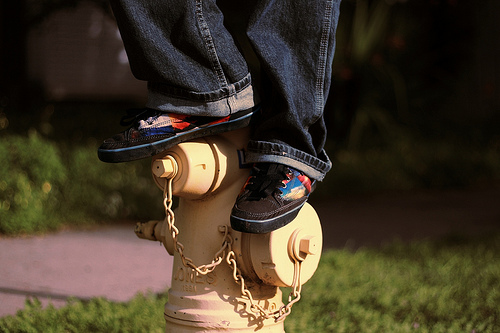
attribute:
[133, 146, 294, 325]
hydrant — fire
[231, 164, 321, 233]
shoestrings — black, tennis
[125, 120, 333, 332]
fire hydrant — light yellow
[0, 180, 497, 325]
sidewalk — cement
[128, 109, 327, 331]
hydrant — fire, yellow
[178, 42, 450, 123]
jeans — dark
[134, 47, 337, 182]
pants — rolled up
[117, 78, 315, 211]
black shoes — his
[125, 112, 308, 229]
shoes — black, his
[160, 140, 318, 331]
hydrant — fire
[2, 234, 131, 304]
sidewalk — empty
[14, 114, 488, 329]
grass — dark green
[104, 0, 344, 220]
jeans — dark blue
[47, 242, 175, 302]
sidewalk — grey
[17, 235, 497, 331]
grass — green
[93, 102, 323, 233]
tennis shoes — colorful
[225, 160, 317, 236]
shoe — black, converse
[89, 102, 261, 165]
shoe — converse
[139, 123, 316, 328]
hydrant — yellow, fire, tan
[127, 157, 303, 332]
hydrant — fire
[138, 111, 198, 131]
design — red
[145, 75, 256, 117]
cuffs — rolled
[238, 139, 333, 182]
cuffs — rolled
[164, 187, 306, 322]
chain — yellow